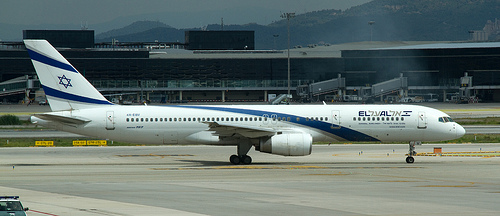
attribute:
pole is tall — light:
[279, 9, 299, 104]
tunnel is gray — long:
[297, 73, 348, 98]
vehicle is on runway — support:
[0, 191, 29, 215]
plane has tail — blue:
[21, 36, 112, 112]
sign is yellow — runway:
[34, 138, 55, 148]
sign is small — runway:
[70, 138, 88, 148]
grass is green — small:
[449, 113, 499, 128]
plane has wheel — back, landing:
[229, 153, 241, 165]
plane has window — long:
[124, 117, 131, 124]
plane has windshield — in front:
[436, 115, 454, 125]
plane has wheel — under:
[225, 152, 236, 161]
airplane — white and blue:
[1, 46, 464, 196]